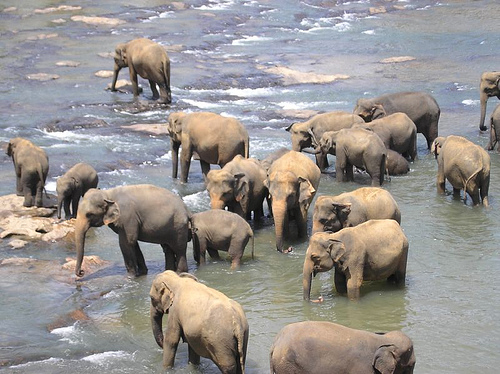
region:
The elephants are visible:
[279, 144, 391, 282]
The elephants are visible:
[203, 159, 341, 344]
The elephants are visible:
[223, 160, 304, 290]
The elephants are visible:
[185, 82, 282, 193]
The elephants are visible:
[241, 234, 318, 326]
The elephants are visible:
[262, 182, 337, 362]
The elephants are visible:
[159, 186, 264, 282]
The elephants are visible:
[96, 139, 327, 364]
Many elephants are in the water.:
[7, 28, 468, 373]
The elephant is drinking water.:
[95, 28, 180, 108]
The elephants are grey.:
[6, 74, 465, 372]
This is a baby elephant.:
[181, 203, 261, 275]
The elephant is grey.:
[61, 181, 197, 273]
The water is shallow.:
[43, 30, 472, 357]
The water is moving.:
[190, 26, 380, 96]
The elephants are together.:
[8, 51, 463, 353]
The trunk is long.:
[130, 293, 182, 363]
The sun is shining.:
[20, 21, 496, 361]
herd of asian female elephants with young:
[10, 17, 495, 370]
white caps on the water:
[180, 0, 376, 65]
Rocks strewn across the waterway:
[15, 10, 125, 145]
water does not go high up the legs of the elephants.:
[0, 244, 495, 372]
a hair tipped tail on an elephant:
[453, 148, 488, 210]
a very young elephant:
[51, 148, 113, 223]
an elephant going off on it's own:
[63, 24, 205, 109]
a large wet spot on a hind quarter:
[185, 288, 252, 372]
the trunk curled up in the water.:
[290, 220, 387, 325]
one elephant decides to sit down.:
[340, 85, 437, 185]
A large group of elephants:
[0, 8, 496, 363]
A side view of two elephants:
[286, 180, 421, 297]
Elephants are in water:
[0, 30, 495, 370]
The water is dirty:
[410, 206, 496, 356]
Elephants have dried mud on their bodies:
[211, 147, 421, 302]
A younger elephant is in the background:
[41, 155, 101, 225]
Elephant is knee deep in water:
[280, 217, 425, 312]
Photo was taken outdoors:
[5, 5, 492, 355]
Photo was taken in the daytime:
[11, 7, 493, 369]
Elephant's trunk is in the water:
[290, 260, 334, 307]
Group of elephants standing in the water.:
[5, 20, 497, 372]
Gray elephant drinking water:
[102, 37, 179, 99]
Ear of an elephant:
[155, 285, 177, 307]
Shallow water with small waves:
[186, 9, 391, 91]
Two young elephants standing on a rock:
[10, 128, 100, 228]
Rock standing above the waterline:
[3, 193, 86, 269]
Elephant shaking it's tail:
[434, 132, 493, 204]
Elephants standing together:
[291, 95, 419, 170]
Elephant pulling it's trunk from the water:
[265, 130, 307, 252]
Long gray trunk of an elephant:
[294, 260, 325, 300]